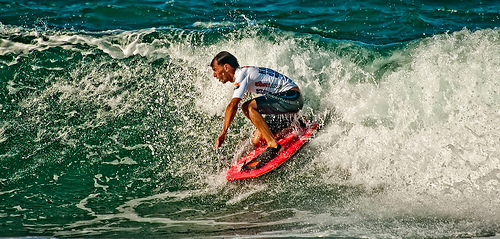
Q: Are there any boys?
A: No, there are no boys.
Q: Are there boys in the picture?
A: No, there are no boys.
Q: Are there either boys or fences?
A: No, there are no boys or fences.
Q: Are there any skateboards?
A: No, there are no skateboards.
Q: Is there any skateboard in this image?
A: No, there are no skateboards.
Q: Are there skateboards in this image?
A: No, there are no skateboards.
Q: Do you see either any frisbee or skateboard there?
A: No, there are no skateboards or frisbees.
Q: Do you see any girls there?
A: No, there are no girls.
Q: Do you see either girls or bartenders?
A: No, there are no girls or bartenders.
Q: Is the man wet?
A: Yes, the man is wet.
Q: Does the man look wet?
A: Yes, the man is wet.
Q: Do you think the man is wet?
A: Yes, the man is wet.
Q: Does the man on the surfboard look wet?
A: Yes, the man is wet.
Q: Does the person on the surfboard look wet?
A: Yes, the man is wet.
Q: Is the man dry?
A: No, the man is wet.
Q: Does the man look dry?
A: No, the man is wet.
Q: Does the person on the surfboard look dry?
A: No, the man is wet.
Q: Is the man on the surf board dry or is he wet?
A: The man is wet.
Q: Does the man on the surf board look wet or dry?
A: The man is wet.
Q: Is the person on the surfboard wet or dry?
A: The man is wet.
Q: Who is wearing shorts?
A: The man is wearing shorts.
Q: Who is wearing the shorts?
A: The man is wearing shorts.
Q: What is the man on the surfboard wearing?
A: The man is wearing shorts.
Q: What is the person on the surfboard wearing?
A: The man is wearing shorts.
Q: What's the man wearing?
A: The man is wearing shorts.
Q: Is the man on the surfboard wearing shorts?
A: Yes, the man is wearing shorts.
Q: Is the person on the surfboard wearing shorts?
A: Yes, the man is wearing shorts.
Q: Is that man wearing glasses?
A: No, the man is wearing shorts.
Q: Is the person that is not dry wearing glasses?
A: No, the man is wearing shorts.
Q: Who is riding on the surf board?
A: The man is riding on the surf board.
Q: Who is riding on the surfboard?
A: The man is riding on the surf board.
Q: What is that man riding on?
A: The man is riding on the surfboard.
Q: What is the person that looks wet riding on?
A: The man is riding on the surfboard.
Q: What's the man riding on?
A: The man is riding on the surfboard.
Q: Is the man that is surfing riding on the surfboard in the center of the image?
A: Yes, the man is riding on the surfboard.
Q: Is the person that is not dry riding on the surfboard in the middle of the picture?
A: Yes, the man is riding on the surfboard.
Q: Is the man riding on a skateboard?
A: No, the man is riding on the surfboard.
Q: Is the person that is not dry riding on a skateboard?
A: No, the man is riding on the surfboard.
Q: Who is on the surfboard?
A: The man is on the surfboard.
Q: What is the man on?
A: The man is on the surfboard.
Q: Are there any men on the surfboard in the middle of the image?
A: Yes, there is a man on the surfboard.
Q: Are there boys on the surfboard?
A: No, there is a man on the surfboard.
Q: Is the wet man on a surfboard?
A: Yes, the man is on a surfboard.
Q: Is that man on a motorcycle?
A: No, the man is on a surfboard.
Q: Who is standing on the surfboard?
A: The man is standing on the surfboard.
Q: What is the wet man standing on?
A: The man is standing on the surfboard.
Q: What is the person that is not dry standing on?
A: The man is standing on the surfboard.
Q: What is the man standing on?
A: The man is standing on the surfboard.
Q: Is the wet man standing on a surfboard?
A: Yes, the man is standing on a surfboard.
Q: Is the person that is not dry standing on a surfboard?
A: Yes, the man is standing on a surfboard.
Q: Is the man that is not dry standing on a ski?
A: No, the man is standing on a surfboard.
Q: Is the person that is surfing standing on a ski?
A: No, the man is standing on a surfboard.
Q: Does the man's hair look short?
A: Yes, the hair is short.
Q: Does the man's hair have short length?
A: Yes, the hair is short.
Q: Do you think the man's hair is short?
A: Yes, the hair is short.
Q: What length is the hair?
A: The hair is short.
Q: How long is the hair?
A: The hair is short.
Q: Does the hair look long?
A: No, the hair is short.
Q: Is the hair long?
A: No, the hair is short.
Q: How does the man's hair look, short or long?
A: The hair is short.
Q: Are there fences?
A: No, there are no fences.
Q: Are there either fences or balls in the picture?
A: No, there are no fences or balls.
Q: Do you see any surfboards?
A: Yes, there is a surfboard.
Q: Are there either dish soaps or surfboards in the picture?
A: Yes, there is a surfboard.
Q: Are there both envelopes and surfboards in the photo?
A: No, there is a surfboard but no envelopes.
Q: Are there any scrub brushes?
A: No, there are no scrub brushes.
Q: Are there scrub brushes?
A: No, there are no scrub brushes.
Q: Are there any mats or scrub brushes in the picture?
A: No, there are no scrub brushes or mats.